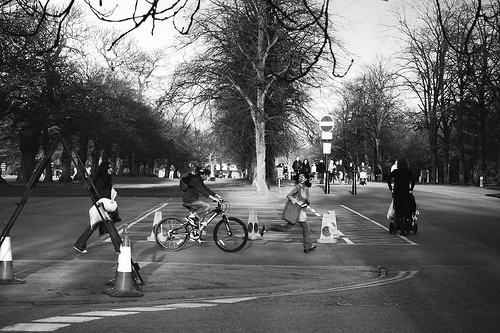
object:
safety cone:
[0, 228, 28, 285]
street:
[0, 178, 500, 333]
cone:
[103, 225, 144, 298]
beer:
[432, 294, 458, 313]